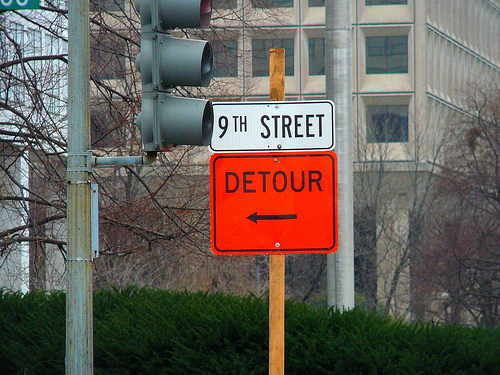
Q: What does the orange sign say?
A: Detour.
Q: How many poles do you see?
A: Three.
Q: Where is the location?
A: 9th Street.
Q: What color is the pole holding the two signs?
A: Yellow.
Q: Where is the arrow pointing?
A: Left.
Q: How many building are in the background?
A: Two.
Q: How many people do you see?
A: None.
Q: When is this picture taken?
A: In the Daytime.